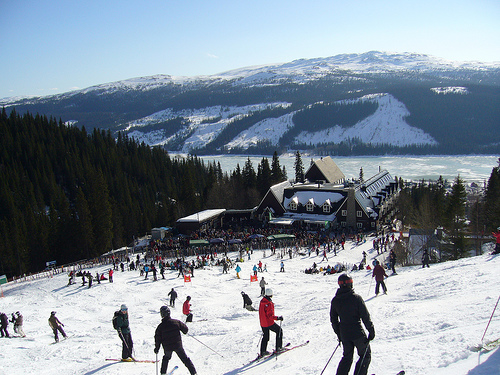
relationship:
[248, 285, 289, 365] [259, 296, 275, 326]
person wearing coat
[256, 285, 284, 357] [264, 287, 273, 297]
person wearing hat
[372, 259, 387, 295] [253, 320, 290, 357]
person holding ski poles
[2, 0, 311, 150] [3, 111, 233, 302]
trees on hillside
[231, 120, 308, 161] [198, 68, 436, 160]
snow on mountain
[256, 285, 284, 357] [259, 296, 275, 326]
person wearing coat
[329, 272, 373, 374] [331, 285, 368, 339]
people wearing jacket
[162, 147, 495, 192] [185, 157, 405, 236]
lake behind building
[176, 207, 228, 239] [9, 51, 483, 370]
building in mountains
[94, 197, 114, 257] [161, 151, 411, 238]
tree surrounding lodge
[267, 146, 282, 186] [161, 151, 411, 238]
tree surrounding lodge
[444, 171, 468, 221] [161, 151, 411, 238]
tree surrounding lodge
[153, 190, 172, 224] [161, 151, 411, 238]
tree surrounding lodge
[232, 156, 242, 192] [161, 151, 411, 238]
tree surrounding lodge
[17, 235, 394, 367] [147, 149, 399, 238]
people surrounding lodge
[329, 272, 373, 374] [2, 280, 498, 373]
people taking advantage of snow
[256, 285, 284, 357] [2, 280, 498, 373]
person taking advantage of snow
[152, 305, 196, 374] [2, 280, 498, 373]
person taking advantage of snow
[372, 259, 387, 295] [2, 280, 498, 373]
person taking advantage of snow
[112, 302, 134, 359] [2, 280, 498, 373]
person taking advantage of snow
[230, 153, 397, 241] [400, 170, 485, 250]
building surrounded by trees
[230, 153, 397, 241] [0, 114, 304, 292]
building surrounded by trees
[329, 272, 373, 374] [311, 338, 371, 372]
people extends poles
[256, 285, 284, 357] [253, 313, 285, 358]
person extends poles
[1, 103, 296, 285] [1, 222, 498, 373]
pines frame slope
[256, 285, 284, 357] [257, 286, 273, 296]
person wearing hat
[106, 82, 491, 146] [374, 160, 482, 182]
slopes across water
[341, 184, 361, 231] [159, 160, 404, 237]
chimney on lodge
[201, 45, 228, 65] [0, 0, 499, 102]
clouds in sky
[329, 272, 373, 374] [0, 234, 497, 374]
people standing in snow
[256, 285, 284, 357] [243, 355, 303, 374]
person standing in snow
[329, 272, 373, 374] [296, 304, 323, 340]
people standing in snow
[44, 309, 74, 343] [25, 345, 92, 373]
skier standing in snow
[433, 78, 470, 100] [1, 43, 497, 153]
clearing on mountain